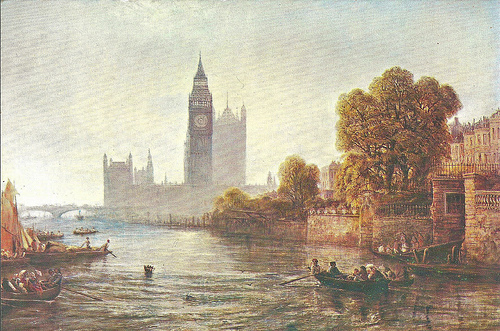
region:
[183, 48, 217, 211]
painting of tall clock tower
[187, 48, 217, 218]
tall clock tower with spires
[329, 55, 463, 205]
light green leaves on large tree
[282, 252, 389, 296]
several people in rowboat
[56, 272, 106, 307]
oar dipped in choppy water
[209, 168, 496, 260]
large stone walls along body of water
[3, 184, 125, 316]
several dark rowboats in water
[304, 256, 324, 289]
man wearing light colored shirt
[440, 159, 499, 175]
line of metal fencing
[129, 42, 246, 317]
body of water with clock tower in background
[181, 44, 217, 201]
A painting of Big Ben.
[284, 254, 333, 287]
A man rowing a boat.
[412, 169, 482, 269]
A passage way for a canal.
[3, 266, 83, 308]
People on a boat.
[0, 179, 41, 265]
The sail of a boat.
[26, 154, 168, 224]
The bridge in London.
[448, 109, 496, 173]
A row of houses.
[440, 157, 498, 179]
Black metal railings along a street.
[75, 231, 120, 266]
Men rowing a boat.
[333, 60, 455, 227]
A tall green and orange tree.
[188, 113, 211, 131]
This is a clock face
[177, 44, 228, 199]
this is a tower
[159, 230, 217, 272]
this is the water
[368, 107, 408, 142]
these are the leaves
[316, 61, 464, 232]
this is a tree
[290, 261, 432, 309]
this is a boat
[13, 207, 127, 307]
these are the boats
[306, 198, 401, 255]
this is a wall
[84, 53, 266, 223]
these are the buildings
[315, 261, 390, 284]
these are the people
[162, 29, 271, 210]
painting of big ben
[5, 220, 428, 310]
people rowing boats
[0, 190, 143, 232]
bridge into city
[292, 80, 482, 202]
trees growing along waters edge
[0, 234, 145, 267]
people rowing goods across water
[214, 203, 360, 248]
brick walls along the water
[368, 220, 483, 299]
boat at a dock unloading people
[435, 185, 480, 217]
sign on brick wall along the water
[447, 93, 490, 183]
buildings overlooking the waterway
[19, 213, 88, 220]
boats passing under a bridge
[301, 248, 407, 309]
people riding a boat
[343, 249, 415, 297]
people riding a boat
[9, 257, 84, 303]
people riding a boat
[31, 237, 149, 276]
people riding a boat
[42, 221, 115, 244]
people riding a boat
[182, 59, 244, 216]
the big Ben in the distance